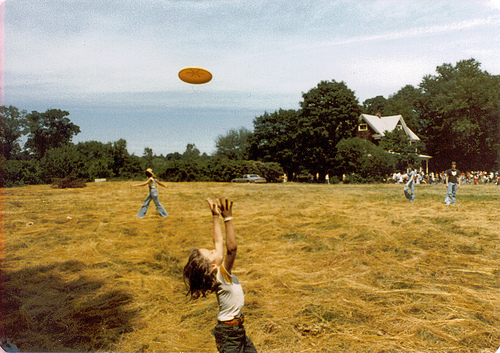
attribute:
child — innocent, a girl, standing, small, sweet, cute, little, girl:
[183, 198, 257, 353]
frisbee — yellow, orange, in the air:
[177, 67, 214, 83]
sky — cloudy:
[1, 1, 499, 157]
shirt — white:
[212, 261, 246, 321]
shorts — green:
[211, 316, 255, 352]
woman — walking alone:
[132, 167, 169, 219]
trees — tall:
[247, 58, 499, 183]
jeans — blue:
[403, 179, 415, 200]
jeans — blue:
[445, 184, 457, 204]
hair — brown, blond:
[181, 247, 221, 299]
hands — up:
[204, 196, 234, 215]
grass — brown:
[0, 184, 499, 352]